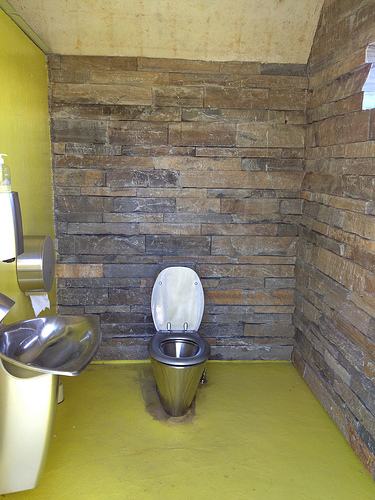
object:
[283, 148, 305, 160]
bricks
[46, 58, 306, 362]
wall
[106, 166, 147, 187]
brick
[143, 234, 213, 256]
brick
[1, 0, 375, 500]
bathroom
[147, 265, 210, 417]
toilet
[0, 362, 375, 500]
green floor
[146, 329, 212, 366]
seat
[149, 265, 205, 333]
lid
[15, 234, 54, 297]
toilet dispenser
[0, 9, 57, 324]
wall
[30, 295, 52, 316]
toilet paper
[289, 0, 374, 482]
wall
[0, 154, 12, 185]
plastic bottle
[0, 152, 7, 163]
pump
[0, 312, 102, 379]
sink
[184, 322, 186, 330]
hinge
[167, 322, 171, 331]
hinge